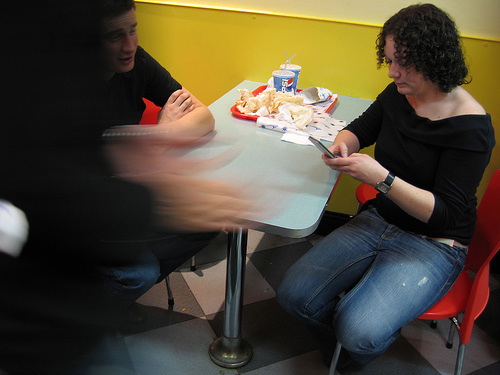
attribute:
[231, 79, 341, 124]
tray — red, plastic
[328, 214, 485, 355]
jeans — blue, denim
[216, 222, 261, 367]
pole — gray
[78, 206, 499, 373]
floor — black and white, checkered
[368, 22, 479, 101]
curly hair — on woman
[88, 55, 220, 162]
arms — crossed